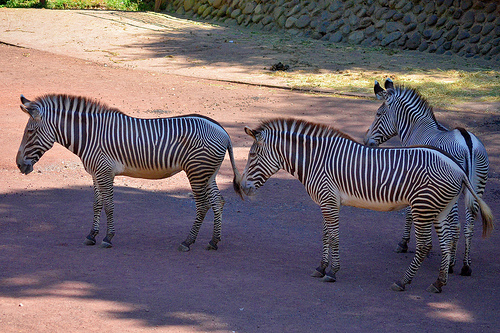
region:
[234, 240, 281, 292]
part of the ground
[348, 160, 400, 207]
stomach of a zebra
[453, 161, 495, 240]
tail of a zebra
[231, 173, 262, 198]
mouth of a zebra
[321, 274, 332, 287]
hoof of a zebra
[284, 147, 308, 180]
neck of a giraffe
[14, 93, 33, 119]
left ear of a zebra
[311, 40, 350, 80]
part of a floor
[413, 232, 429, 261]
part of a knee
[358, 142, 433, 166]
back of a zebra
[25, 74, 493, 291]
Three walking zebras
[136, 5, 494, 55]
Stone wall behind zebras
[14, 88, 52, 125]
Black and white zebra ears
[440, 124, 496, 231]
Black and white zebra tails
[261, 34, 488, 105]
Grassy patch behind zebras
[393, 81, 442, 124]
Black and white zebra mane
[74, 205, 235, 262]
Black and white zebra hooves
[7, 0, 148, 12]
Patch of green grass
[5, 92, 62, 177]
Black and white zebra head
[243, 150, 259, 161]
Small zebra eye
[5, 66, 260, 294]
zebra is very small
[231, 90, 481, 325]
zebra is very small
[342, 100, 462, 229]
zebra is very small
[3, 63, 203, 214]
zebra is very small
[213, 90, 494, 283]
zebra is black and white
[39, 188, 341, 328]
ground is brown dirt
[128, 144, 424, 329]
ground is brown dirt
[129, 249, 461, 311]
ground is brown dirt